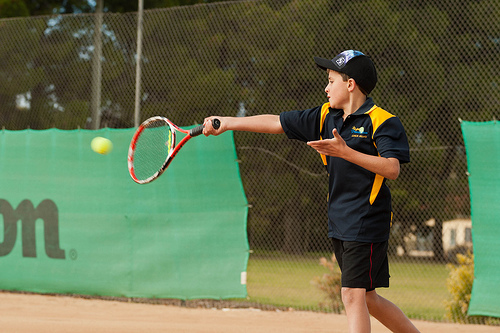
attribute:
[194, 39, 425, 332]
boy — playing, young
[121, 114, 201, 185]
tennis racket — red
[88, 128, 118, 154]
ball — green, yellow, flying, up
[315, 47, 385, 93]
hat — blue, black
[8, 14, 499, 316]
fence — chain link, metal, green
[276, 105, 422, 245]
shirt — yellow, black, dark, blue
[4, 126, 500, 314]
material — green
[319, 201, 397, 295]
shorts — black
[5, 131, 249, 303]
sign — green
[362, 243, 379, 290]
stripe — red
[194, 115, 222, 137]
handle — black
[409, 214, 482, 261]
house — white, peeking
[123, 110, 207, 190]
tennis racket — red, black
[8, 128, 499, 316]
tarp — green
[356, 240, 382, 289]
line — red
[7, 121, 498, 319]
banner — long, green, promotional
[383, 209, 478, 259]
building — behind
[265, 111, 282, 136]
elbow — straight